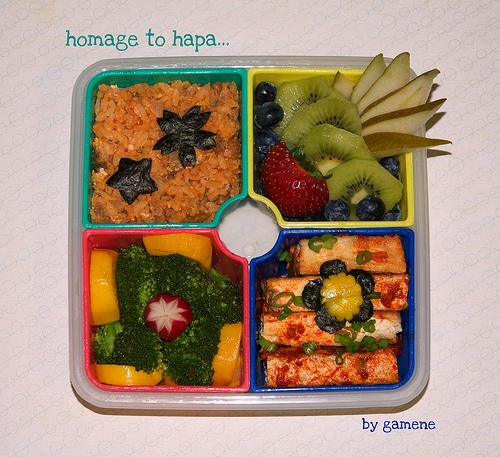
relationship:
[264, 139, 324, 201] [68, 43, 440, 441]
strawberry in container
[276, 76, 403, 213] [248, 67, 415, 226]
kiwi in container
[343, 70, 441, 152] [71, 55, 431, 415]
pears in container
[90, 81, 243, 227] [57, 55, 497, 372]
rice in container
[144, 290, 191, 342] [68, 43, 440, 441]
radish in container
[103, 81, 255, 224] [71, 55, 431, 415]
rice in container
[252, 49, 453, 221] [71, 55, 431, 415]
fruit in container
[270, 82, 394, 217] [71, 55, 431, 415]
fruit in container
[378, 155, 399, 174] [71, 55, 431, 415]
blueberry in container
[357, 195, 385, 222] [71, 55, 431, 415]
blueberry in container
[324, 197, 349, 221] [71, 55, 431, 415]
blueberry in container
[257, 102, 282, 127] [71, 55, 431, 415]
blueberry in container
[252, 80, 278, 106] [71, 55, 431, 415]
blueberry in container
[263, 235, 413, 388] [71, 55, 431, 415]
burritos in container